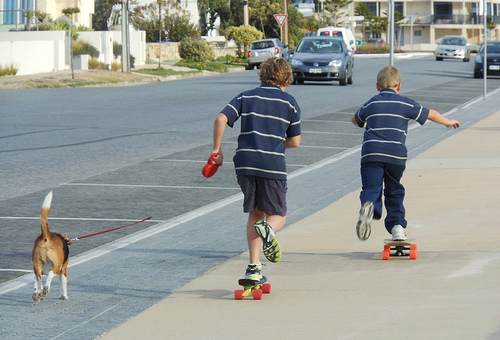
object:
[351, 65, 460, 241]
boy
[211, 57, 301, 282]
boy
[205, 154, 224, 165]
handle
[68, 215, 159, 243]
leash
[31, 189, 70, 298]
dog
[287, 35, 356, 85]
car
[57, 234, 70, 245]
collar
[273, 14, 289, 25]
sign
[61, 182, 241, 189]
line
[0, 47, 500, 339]
street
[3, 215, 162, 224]
line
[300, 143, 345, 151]
line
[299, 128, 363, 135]
line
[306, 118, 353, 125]
line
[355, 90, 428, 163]
shirt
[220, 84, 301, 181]
shirt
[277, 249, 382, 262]
shadow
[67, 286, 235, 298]
shadow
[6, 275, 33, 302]
shadow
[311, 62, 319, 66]
logo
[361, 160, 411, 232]
pants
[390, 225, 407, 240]
shoe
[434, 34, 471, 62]
car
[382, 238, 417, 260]
skateboard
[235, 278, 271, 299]
skateboard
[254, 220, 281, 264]
tennis shoe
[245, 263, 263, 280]
tennis shoe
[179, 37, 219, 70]
bush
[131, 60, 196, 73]
sidewalk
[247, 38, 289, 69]
car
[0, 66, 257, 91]
curb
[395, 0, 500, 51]
building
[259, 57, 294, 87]
hair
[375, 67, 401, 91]
hair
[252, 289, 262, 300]
wheel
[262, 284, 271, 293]
wheel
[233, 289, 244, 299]
wheel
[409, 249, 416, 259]
wheel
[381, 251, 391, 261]
wheel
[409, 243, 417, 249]
wheel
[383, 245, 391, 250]
wheel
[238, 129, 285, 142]
stripe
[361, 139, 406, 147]
stripe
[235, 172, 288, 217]
shorts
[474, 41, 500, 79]
car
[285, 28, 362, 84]
van